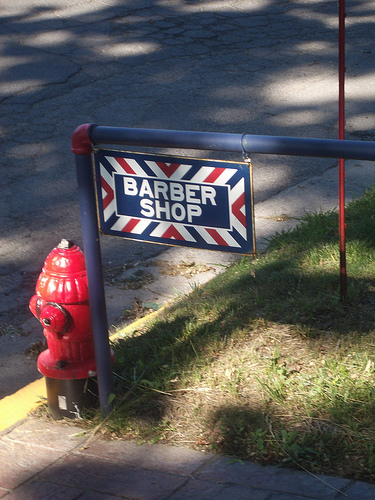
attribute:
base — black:
[35, 386, 107, 433]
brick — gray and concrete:
[32, 452, 124, 459]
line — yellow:
[17, 362, 38, 451]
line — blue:
[227, 226, 246, 249]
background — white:
[100, 154, 247, 248]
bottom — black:
[42, 375, 99, 422]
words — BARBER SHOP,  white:
[125, 179, 217, 223]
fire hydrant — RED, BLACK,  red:
[28, 238, 96, 423]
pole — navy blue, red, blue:
[66, 123, 374, 160]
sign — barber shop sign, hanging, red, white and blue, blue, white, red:
[89, 145, 257, 256]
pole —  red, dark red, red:
[337, 1, 349, 308]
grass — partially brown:
[87, 176, 374, 481]